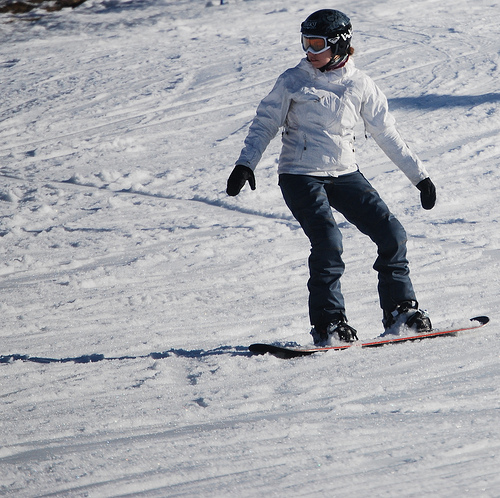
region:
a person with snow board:
[234, 9, 461, 359]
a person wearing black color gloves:
[221, 159, 261, 199]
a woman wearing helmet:
[291, 8, 355, 70]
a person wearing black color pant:
[281, 164, 409, 299]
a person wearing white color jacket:
[271, 66, 408, 173]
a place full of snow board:
[50, 62, 217, 299]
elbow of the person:
[248, 98, 281, 142]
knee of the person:
[306, 219, 411, 256]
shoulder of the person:
[275, 61, 313, 97]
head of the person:
[289, 9, 354, 70]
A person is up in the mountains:
[26, 8, 482, 476]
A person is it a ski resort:
[40, 6, 490, 491]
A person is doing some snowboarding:
[47, 8, 492, 444]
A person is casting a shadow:
[6, 7, 497, 474]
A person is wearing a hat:
[0, 8, 486, 446]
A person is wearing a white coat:
[35, 5, 490, 456]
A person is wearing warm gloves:
[53, 10, 489, 450]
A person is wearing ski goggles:
[45, 13, 481, 463]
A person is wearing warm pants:
[20, 3, 496, 449]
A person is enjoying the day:
[49, 14, 481, 454]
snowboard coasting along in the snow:
[221, 5, 488, 356]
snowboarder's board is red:
[248, 308, 498, 363]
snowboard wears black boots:
[302, 300, 437, 350]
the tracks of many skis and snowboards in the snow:
[6, 28, 491, 232]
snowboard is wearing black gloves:
[216, 158, 445, 210]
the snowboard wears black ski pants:
[273, 165, 427, 325]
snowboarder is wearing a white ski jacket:
[231, 55, 433, 189]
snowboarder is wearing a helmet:
[296, 6, 354, 43]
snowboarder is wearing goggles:
[295, 30, 357, 58]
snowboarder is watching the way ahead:
[294, 5, 359, 75]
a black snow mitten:
[223, 165, 260, 194]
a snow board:
[249, 313, 489, 360]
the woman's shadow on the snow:
[0, 343, 247, 365]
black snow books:
[310, 300, 436, 345]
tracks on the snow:
[380, 23, 475, 59]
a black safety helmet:
[301, 9, 356, 49]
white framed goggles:
[299, 34, 332, 51]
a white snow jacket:
[237, 58, 430, 180]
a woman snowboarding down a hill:
[225, 10, 490, 355]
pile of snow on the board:
[323, 333, 351, 350]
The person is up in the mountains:
[17, 7, 485, 487]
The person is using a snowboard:
[13, 6, 488, 491]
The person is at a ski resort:
[28, 7, 493, 473]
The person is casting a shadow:
[30, 3, 470, 438]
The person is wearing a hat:
[55, 20, 492, 473]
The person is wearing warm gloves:
[62, 6, 490, 477]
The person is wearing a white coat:
[51, 8, 488, 485]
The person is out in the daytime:
[61, 13, 471, 469]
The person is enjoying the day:
[54, 8, 476, 467]